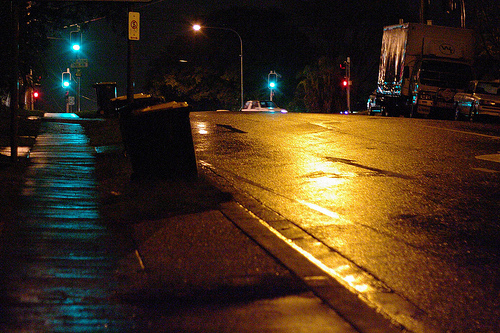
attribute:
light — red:
[33, 91, 40, 100]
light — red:
[341, 78, 350, 86]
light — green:
[267, 81, 277, 90]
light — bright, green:
[72, 42, 81, 52]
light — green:
[63, 79, 70, 90]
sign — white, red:
[127, 12, 141, 42]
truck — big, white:
[377, 23, 474, 119]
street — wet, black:
[188, 110, 499, 332]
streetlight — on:
[192, 23, 244, 113]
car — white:
[242, 99, 289, 115]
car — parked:
[455, 78, 499, 121]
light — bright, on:
[191, 24, 202, 31]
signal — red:
[337, 62, 346, 70]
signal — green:
[266, 72, 277, 93]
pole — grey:
[238, 53, 244, 108]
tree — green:
[300, 57, 341, 113]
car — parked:
[366, 88, 407, 115]